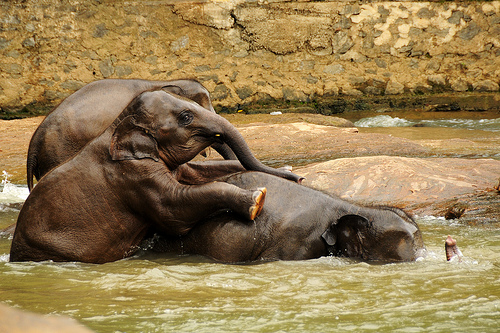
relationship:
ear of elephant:
[105, 110, 162, 164] [9, 89, 304, 264]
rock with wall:
[271, 115, 431, 198] [91, 46, 498, 144]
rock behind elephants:
[3, 2, 498, 125] [16, 63, 473, 275]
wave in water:
[369, 101, 421, 130] [164, 276, 424, 331]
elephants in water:
[8, 78, 462, 265] [2, 110, 499, 330]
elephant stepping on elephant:
[9, 89, 304, 264] [137, 171, 463, 262]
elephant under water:
[152, 171, 459, 266] [2, 200, 494, 329]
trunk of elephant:
[201, 106, 331, 187] [9, 89, 304, 264]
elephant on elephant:
[9, 89, 304, 264] [149, 167, 458, 264]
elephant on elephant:
[26, 78, 236, 192] [149, 167, 458, 264]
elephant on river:
[149, 167, 458, 264] [0, 108, 498, 330]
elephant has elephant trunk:
[4, 89, 309, 294] [222, 121, 307, 185]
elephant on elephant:
[4, 89, 309, 294] [213, 169, 471, 306]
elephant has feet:
[9, 89, 304, 264] [241, 187, 267, 222]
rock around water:
[0, 0, 497, 120] [411, 109, 462, 121]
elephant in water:
[26, 78, 236, 192] [2, 200, 494, 329]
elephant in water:
[9, 89, 304, 264] [2, 200, 494, 329]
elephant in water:
[152, 171, 459, 266] [2, 200, 494, 329]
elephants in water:
[8, 78, 462, 265] [207, 285, 315, 320]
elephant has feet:
[9, 89, 304, 264] [186, 178, 267, 223]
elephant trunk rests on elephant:
[222, 122, 308, 184] [13, 87, 327, 267]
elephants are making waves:
[11, 73, 421, 263] [138, 270, 292, 314]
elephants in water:
[11, 73, 421, 263] [316, 272, 497, 329]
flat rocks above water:
[1, 114, 498, 227] [2, 110, 499, 330]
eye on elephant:
[178, 111, 192, 123] [9, 89, 304, 264]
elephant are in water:
[9, 89, 304, 264] [2, 110, 499, 330]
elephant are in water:
[149, 167, 458, 264] [2, 110, 499, 330]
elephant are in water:
[26, 78, 236, 192] [2, 110, 499, 330]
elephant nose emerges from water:
[441, 233, 461, 256] [424, 264, 471, 295]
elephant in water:
[152, 171, 459, 266] [2, 110, 499, 330]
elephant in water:
[9, 89, 304, 264] [2, 110, 499, 330]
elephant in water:
[27, 66, 220, 191] [2, 110, 499, 330]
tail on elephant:
[25, 124, 42, 193] [26, 78, 236, 192]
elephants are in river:
[8, 78, 462, 265] [9, 100, 491, 317]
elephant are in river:
[26, 78, 236, 192] [9, 100, 491, 317]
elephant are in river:
[152, 171, 459, 266] [9, 100, 491, 317]